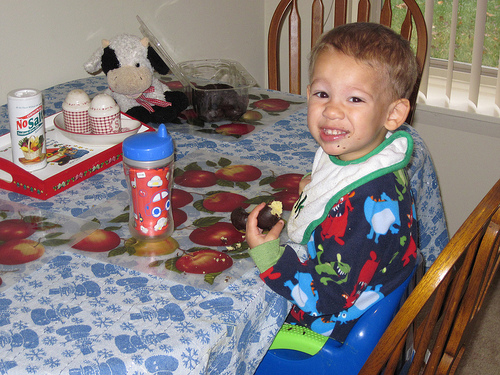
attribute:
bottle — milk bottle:
[121, 122, 176, 241]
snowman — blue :
[28, 295, 87, 335]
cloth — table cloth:
[27, 70, 412, 372]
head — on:
[283, 20, 428, 160]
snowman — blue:
[0, 327, 40, 351]